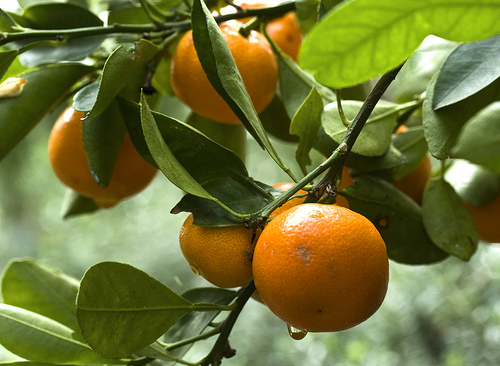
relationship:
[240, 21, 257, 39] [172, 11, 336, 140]
stem of orange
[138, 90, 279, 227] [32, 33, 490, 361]
leaf on tree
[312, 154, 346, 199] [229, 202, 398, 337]
stem of fruit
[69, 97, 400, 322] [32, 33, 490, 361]
fruits i tree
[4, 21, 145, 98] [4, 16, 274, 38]
leaves on branch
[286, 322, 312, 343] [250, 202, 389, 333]
water drop hanging from fruit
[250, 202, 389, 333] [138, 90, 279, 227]
fruit amongst leaf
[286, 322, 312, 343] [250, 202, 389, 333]
water drop on fruit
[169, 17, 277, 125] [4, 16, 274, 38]
fruit attached to branch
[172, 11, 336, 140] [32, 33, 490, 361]
orange attached to tree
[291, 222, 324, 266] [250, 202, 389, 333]
bruise on fruit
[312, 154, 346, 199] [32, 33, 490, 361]
stem of tree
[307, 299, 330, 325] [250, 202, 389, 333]
spot on fruit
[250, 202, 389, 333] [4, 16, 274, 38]
fruit on branch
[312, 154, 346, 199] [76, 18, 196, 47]
stem of leave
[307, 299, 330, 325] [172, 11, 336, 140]
spot on orange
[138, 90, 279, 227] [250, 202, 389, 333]
leaf around fruit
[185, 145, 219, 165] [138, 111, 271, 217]
spot on leaf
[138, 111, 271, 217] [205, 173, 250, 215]
leaf has lines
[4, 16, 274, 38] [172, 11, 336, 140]
branch attached to orange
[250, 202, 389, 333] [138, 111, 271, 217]
fruit on leaf